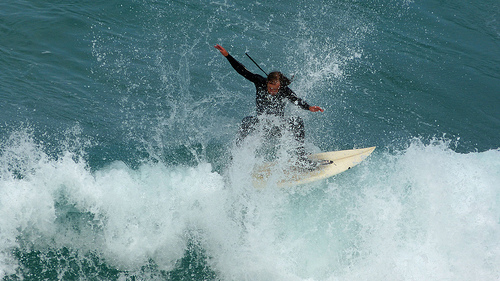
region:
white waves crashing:
[20, 135, 197, 263]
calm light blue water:
[15, 17, 174, 129]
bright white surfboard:
[257, 130, 385, 189]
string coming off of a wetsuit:
[240, 47, 277, 81]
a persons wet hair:
[265, 65, 298, 90]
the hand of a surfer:
[211, 36, 232, 62]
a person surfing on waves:
[201, 31, 380, 199]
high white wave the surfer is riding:
[147, 111, 491, 279]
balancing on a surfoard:
[203, 36, 370, 212]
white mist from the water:
[105, 39, 222, 179]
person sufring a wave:
[191, 38, 392, 199]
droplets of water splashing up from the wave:
[86, 29, 226, 155]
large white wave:
[1, 136, 498, 278]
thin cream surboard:
[227, 146, 378, 186]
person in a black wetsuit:
[196, 30, 344, 169]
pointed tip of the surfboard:
[367, 142, 379, 156]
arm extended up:
[199, 34, 259, 94]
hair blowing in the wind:
[284, 73, 296, 88]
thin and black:
[244, 51, 270, 74]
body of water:
[1, 1, 496, 279]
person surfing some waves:
[181, 36, 406, 229]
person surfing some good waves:
[164, 30, 396, 235]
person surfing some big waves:
[172, 6, 412, 239]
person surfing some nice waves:
[145, 20, 398, 234]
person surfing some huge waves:
[159, 26, 409, 224]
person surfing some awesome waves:
[141, 26, 426, 243]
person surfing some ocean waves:
[134, 24, 403, 242]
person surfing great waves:
[148, 26, 396, 235]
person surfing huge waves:
[151, 32, 405, 254]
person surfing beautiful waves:
[148, 16, 421, 242]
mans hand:
[201, 40, 243, 61]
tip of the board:
[354, 140, 385, 157]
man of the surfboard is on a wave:
[178, 17, 383, 218]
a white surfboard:
[233, 161, 406, 191]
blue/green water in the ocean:
[3, 53, 118, 123]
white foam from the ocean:
[48, 151, 239, 263]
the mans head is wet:
[253, 58, 292, 100]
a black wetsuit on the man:
[221, 44, 338, 175]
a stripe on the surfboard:
[331, 151, 367, 163]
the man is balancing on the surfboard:
[204, 40, 429, 235]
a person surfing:
[215, 48, 392, 203]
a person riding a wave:
[164, 35, 455, 207]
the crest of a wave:
[10, 130, 449, 266]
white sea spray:
[101, 22, 234, 160]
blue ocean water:
[352, 48, 470, 133]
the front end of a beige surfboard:
[307, 128, 418, 188]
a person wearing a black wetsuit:
[234, 55, 333, 170]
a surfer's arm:
[202, 31, 262, 89]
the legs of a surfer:
[227, 111, 357, 179]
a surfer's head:
[246, 60, 303, 109]